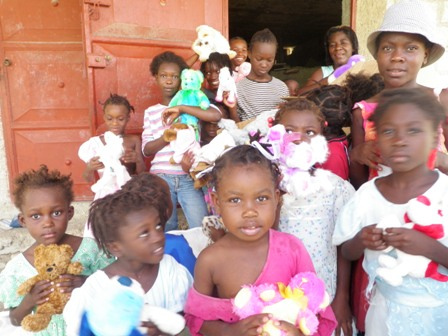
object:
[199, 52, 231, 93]
girl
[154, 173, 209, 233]
pants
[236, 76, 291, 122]
gray shirt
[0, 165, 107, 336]
child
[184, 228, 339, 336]
t shirt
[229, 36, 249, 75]
child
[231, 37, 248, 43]
hair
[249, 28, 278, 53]
hair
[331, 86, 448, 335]
child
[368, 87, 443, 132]
hair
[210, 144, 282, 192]
hair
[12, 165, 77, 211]
hair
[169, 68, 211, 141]
bear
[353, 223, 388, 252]
hand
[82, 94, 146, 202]
child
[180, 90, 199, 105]
blue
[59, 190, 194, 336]
child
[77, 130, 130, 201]
white bear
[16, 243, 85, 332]
bear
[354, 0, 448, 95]
wall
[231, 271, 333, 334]
animal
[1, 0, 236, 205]
door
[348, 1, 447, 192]
person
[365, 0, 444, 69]
hat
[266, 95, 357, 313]
girl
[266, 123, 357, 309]
teddy bear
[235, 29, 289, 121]
child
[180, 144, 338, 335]
child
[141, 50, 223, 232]
child